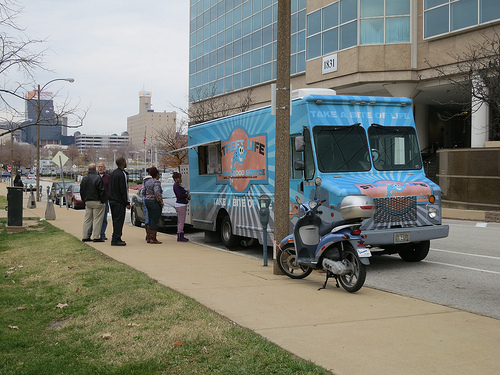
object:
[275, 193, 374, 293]
motor scooter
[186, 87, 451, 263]
food truck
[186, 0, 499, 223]
building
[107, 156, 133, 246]
man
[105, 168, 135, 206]
jacket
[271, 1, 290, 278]
street light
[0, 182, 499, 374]
sidewalk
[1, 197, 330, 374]
grass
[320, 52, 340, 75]
sign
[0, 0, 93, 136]
tree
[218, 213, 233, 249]
left rear tire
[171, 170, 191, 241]
person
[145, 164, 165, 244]
woman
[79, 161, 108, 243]
man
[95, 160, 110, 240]
man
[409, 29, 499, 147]
tree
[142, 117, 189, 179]
tree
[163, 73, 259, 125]
tree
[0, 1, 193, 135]
sky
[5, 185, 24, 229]
trash bin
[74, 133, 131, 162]
building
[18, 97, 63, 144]
building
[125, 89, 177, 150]
building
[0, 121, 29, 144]
building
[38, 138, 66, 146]
building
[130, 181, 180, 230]
car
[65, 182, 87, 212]
car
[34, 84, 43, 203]
lamp post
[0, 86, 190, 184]
city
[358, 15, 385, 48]
window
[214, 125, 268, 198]
sign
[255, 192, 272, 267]
parking meter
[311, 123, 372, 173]
windshield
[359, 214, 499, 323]
road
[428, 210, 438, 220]
headlight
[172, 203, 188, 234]
pants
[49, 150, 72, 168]
road sign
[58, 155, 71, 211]
post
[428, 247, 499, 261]
line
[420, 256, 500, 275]
line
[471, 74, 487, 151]
pillar